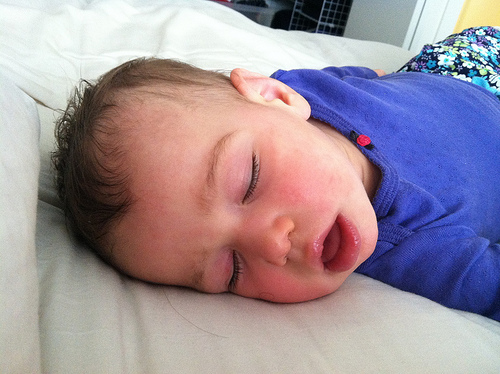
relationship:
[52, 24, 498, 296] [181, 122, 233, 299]
baby has eyebrows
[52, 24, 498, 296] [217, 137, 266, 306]
baby has eyes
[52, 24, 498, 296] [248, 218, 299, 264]
baby has nose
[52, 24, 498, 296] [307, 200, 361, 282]
baby has mouth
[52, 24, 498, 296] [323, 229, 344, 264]
baby has tongue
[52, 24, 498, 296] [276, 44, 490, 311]
baby in shirt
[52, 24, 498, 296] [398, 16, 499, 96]
baby in shorts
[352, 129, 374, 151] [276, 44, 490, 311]
dot on shirt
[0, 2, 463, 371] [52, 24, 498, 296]
sheet under baby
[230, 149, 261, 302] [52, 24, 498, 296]
eyelashes on baby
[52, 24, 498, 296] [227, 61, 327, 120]
baby has ears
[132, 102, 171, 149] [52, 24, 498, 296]
spots on baby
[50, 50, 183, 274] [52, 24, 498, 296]
hair on baby